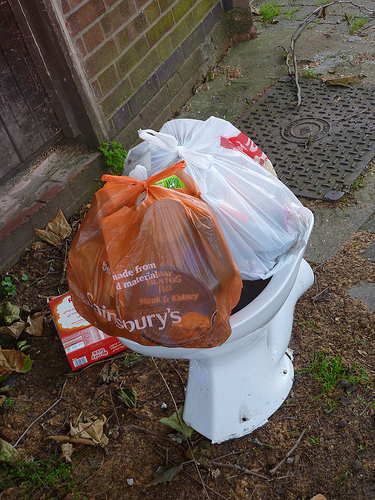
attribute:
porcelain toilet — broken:
[229, 304, 301, 424]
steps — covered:
[3, 139, 103, 270]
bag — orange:
[30, 164, 249, 358]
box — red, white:
[34, 280, 131, 375]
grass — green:
[350, 12, 374, 37]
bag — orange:
[65, 159, 242, 347]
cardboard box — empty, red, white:
[48, 295, 98, 341]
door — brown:
[0, 0, 101, 198]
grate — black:
[225, 71, 373, 207]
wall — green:
[63, 6, 234, 155]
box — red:
[46, 292, 133, 373]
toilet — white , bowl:
[117, 207, 314, 442]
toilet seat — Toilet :
[114, 200, 313, 443]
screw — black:
[238, 414, 248, 422]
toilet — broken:
[93, 205, 321, 451]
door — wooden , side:
[0, 10, 72, 182]